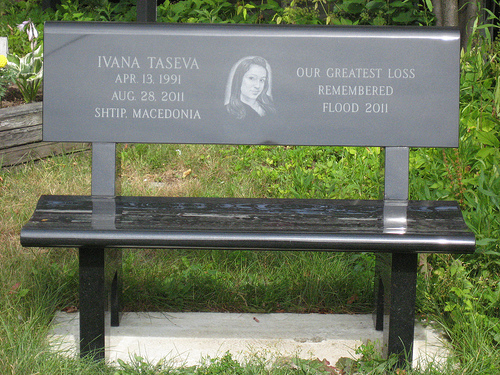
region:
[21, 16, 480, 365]
A grey stone bench outside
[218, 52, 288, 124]
Picture of girl on bench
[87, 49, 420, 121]
Writing in remembrance of girl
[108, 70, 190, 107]
Birth and death dates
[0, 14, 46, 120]
Flowers growing in ground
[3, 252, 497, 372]
Grass growing around bench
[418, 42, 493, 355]
Bushes growing behind bench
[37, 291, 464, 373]
Cement slap under bench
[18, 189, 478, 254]
Black seat of bench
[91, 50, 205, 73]
Name of the girl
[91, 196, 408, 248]
this is a bench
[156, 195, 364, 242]
the bench is metallic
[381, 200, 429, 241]
the bench is shiny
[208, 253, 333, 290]
this is the grass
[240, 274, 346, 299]
the grass is green in color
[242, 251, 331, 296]
the grass is long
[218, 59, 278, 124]
this is the drawing of a woman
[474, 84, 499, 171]
these are some leaves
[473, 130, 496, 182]
the leaves are green in color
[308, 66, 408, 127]
the bench has some writings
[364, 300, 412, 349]
part of a stand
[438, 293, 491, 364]
part of some grass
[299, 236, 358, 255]
edge of a bench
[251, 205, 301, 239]
surface of a bench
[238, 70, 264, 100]
part of a drawing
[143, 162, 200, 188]
part of a dry grass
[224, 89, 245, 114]
hair of the lady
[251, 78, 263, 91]
nose of the lady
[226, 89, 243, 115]
hair of a lady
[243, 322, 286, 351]
part of a cemented floor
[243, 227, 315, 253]
edge of a bench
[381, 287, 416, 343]
part of a stand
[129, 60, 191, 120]
part of some writing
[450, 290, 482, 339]
part of some grass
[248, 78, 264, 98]
nose of the lady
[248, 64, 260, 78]
head of the lady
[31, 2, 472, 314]
bench in memory of a person who died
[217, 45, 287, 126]
woman with long hair and a smile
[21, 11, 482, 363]
bench in dark grey and light grey materials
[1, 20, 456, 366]
bench on top of a cement slab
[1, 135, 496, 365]
grass and weeds growing around bench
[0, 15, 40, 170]
yellow and white plants in a wooden planter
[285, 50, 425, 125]
message in grey text using letters and numbers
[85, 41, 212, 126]
information answering who, when and where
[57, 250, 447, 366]
two supports with cutout to create four legs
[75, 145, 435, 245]
reflection of back supports across seat